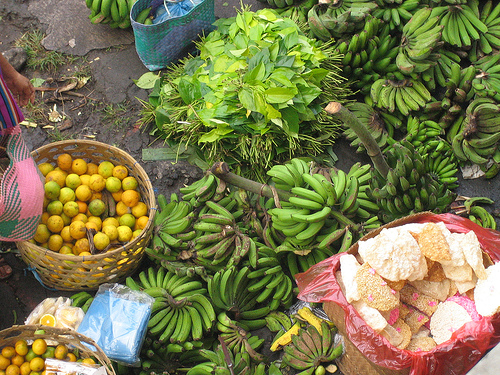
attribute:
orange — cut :
[35, 311, 57, 330]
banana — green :
[438, 156, 451, 170]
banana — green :
[397, 175, 409, 191]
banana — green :
[340, 177, 358, 212]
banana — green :
[301, 171, 323, 196]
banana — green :
[291, 184, 324, 202]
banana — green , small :
[298, 220, 324, 247]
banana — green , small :
[337, 168, 348, 199]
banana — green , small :
[306, 171, 331, 201]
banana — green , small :
[284, 206, 329, 224]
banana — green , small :
[264, 168, 291, 190]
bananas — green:
[251, 146, 425, 247]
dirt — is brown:
[46, 96, 158, 148]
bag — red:
[347, 316, 489, 373]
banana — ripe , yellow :
[295, 297, 328, 337]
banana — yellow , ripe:
[263, 320, 303, 349]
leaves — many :
[170, 10, 338, 162]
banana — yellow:
[297, 307, 327, 334]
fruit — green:
[138, 16, 358, 170]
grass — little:
[87, 85, 150, 132]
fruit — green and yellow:
[48, 145, 140, 257]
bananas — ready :
[269, 153, 379, 256]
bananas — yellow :
[270, 305, 350, 355]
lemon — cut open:
[27, 151, 168, 267]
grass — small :
[96, 95, 143, 130]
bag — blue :
[128, 0, 219, 72]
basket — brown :
[12, 138, 155, 287]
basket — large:
[290, 210, 495, 373]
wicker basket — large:
[6, 139, 160, 296]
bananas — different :
[268, 157, 372, 254]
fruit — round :
[87, 170, 100, 187]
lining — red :
[298, 211, 484, 360]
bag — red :
[298, 211, 482, 371]